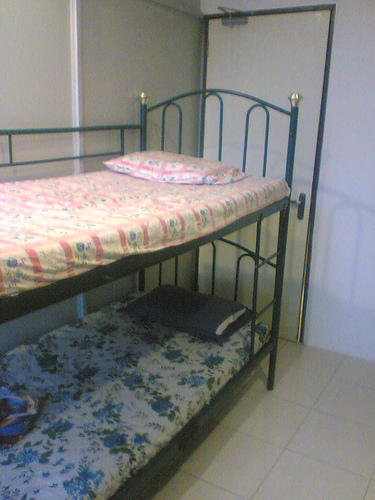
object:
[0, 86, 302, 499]
bunk bed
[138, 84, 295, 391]
metal frame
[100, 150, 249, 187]
bed pillow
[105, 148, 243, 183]
pillowcase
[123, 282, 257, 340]
pillowcase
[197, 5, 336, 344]
bedroom door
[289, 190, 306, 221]
door lever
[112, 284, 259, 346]
pillow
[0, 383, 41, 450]
blanket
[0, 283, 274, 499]
bed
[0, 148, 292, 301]
bed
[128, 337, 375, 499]
floor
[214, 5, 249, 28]
hinge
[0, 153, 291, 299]
sheet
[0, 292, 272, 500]
sheet